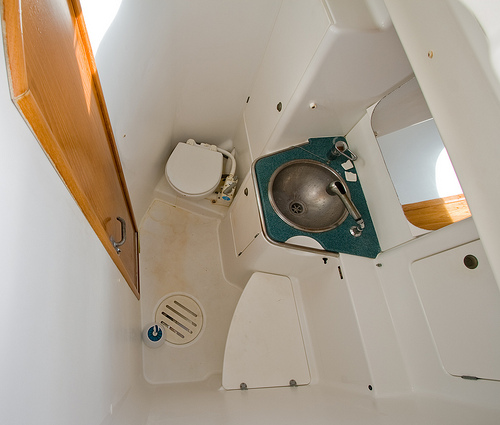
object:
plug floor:
[142, 322, 166, 348]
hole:
[463, 254, 479, 271]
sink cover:
[410, 239, 499, 382]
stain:
[143, 195, 203, 302]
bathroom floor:
[139, 199, 243, 384]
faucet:
[325, 180, 365, 238]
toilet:
[163, 138, 238, 206]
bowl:
[267, 159, 352, 233]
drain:
[155, 295, 203, 345]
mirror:
[370, 76, 473, 232]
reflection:
[434, 146, 472, 222]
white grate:
[151, 290, 206, 348]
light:
[74, 0, 133, 69]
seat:
[221, 272, 317, 391]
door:
[0, 0, 140, 300]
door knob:
[109, 214, 126, 254]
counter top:
[251, 136, 381, 258]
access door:
[228, 171, 261, 258]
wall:
[0, 105, 499, 424]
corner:
[332, 251, 346, 264]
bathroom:
[0, 0, 500, 423]